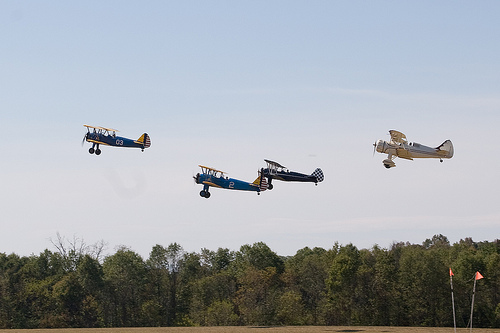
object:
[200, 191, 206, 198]
tire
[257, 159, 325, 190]
plane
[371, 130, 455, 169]
plane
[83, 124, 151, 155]
plane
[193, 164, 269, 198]
airplanes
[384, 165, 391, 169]
tire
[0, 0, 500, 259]
sky